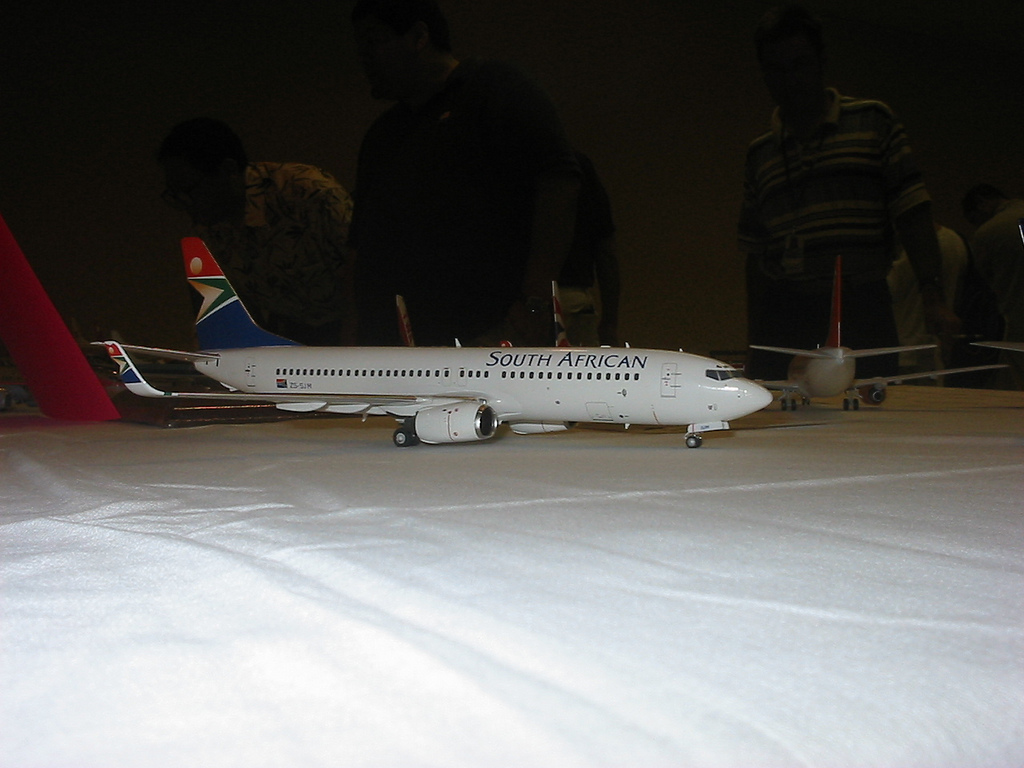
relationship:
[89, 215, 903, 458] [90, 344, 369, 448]
plane has wing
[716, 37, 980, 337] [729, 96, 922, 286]
man has shirt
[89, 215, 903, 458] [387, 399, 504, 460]
plane has engine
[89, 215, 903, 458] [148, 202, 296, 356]
plane has tail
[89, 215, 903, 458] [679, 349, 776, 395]
plane has windshield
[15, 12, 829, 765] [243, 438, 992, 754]
case has floor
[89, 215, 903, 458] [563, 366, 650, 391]
plane has window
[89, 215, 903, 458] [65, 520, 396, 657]
plane on cloth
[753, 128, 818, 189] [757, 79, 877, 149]
lanyard on neck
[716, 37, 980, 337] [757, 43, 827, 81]
man has glasses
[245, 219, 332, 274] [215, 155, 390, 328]
flower on shirt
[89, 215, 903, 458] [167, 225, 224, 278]
plane has tip